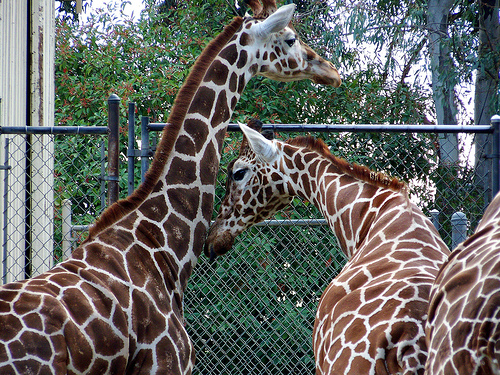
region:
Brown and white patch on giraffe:
[367, 213, 410, 251]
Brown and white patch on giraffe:
[310, 321, 337, 367]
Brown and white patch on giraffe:
[344, 348, 379, 373]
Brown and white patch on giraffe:
[357, 293, 393, 345]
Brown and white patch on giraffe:
[287, 158, 327, 207]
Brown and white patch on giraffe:
[442, 318, 477, 372]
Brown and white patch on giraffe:
[437, 260, 499, 303]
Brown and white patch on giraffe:
[455, 224, 490, 256]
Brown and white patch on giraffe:
[484, 208, 499, 254]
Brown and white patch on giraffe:
[95, 243, 163, 319]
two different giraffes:
[146, 11, 396, 269]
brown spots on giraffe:
[361, 227, 418, 304]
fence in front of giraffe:
[241, 265, 283, 320]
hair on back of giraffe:
[340, 147, 390, 182]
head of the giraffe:
[237, 5, 352, 100]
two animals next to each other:
[141, 28, 400, 268]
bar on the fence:
[383, 108, 422, 144]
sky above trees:
[376, 40, 409, 75]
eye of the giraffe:
[226, 156, 251, 193]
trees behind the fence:
[368, 22, 413, 96]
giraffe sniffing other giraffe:
[178, 116, 375, 274]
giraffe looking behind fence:
[201, 3, 354, 106]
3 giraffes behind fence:
[11, 15, 493, 361]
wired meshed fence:
[8, 119, 118, 201]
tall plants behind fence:
[52, 12, 347, 328]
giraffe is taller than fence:
[71, 5, 372, 171]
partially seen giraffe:
[437, 185, 497, 370]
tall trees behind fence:
[411, 2, 497, 168]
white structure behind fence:
[0, 0, 52, 309]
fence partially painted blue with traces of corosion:
[15, 78, 151, 181]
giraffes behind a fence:
[33, 8, 435, 372]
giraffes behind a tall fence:
[8, 23, 493, 340]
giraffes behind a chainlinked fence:
[21, 4, 478, 371]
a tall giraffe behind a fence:
[59, 29, 492, 360]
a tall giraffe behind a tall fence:
[60, 28, 449, 370]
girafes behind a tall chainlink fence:
[35, 33, 443, 370]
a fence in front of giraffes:
[37, 14, 496, 354]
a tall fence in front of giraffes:
[27, 43, 418, 370]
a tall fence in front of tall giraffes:
[33, 36, 439, 372]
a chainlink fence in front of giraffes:
[44, 33, 445, 373]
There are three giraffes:
[30, 0, 483, 353]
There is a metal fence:
[14, 119, 486, 338]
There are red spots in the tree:
[64, 31, 177, 101]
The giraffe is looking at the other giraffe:
[190, 132, 337, 257]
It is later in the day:
[330, 17, 490, 149]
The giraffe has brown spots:
[21, 226, 167, 348]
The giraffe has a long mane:
[85, 23, 247, 239]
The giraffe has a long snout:
[264, 48, 336, 95]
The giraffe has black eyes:
[233, 162, 248, 184]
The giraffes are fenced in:
[6, 113, 494, 336]